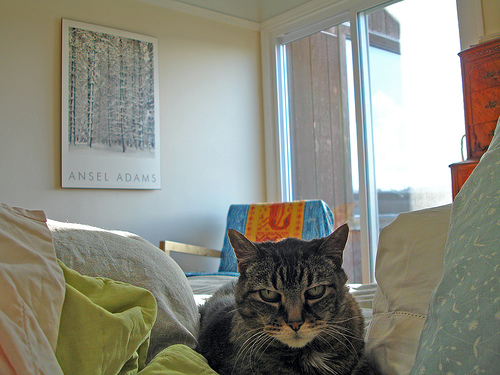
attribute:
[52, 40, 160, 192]
print — Adams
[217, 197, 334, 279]
fabric — blue, orange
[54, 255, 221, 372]
blanket — bight yellow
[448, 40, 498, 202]
hutch — orange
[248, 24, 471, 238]
window — large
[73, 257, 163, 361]
blanket — green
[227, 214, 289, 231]
chair — blue, yellow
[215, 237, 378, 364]
cat — grey, white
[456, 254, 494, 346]
blanket — blue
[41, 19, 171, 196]
poster — Ansel Adams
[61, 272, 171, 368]
blanket — light green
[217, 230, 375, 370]
cat — striped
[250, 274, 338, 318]
eyes — green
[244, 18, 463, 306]
window — large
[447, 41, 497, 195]
chest — tall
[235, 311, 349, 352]
whiskers — white, cat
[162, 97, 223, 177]
wall — beige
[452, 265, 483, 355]
fabric — light, blue, floral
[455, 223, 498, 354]
pattern — white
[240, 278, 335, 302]
eyes — cat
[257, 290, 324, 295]
pupils — dialated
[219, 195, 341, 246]
covering — bright, colored